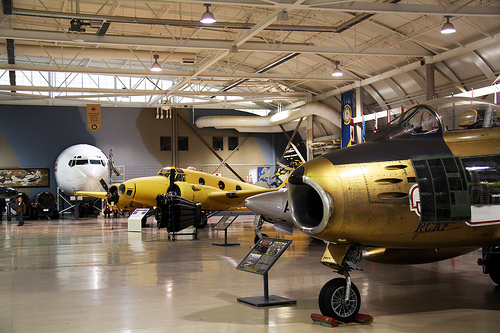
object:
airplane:
[55, 140, 113, 220]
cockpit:
[53, 141, 113, 195]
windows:
[176, 136, 192, 152]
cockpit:
[141, 164, 204, 196]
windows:
[155, 134, 172, 156]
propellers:
[141, 170, 201, 230]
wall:
[0, 103, 272, 191]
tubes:
[193, 101, 343, 133]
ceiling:
[0, 0, 500, 134]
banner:
[336, 84, 362, 151]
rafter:
[35, 58, 364, 95]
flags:
[344, 106, 404, 131]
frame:
[0, 164, 52, 189]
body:
[49, 144, 120, 195]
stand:
[52, 185, 109, 218]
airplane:
[77, 165, 291, 241]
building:
[0, 0, 500, 333]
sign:
[235, 234, 294, 273]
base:
[234, 273, 297, 306]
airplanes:
[244, 98, 500, 333]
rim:
[331, 284, 357, 315]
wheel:
[315, 275, 363, 321]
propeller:
[99, 173, 120, 211]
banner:
[82, 100, 103, 131]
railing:
[2, 3, 500, 98]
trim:
[284, 173, 331, 238]